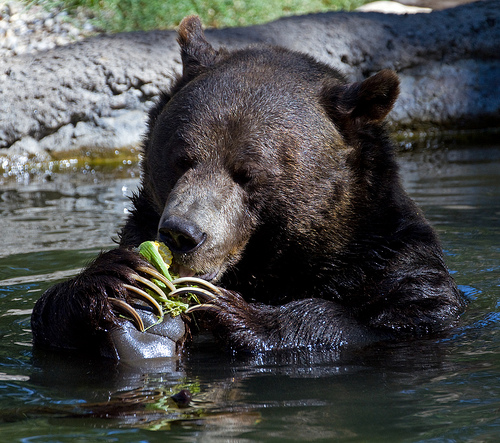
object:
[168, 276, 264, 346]
claws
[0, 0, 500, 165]
ground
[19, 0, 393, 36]
plant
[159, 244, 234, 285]
mouth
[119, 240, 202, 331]
food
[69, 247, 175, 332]
claw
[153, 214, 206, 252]
snout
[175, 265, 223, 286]
tongue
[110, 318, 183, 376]
paws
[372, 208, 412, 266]
fur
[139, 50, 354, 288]
face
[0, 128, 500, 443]
water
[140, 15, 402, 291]
head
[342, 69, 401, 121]
ear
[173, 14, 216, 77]
ear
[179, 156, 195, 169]
eye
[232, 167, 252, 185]
eye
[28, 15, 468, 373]
bear